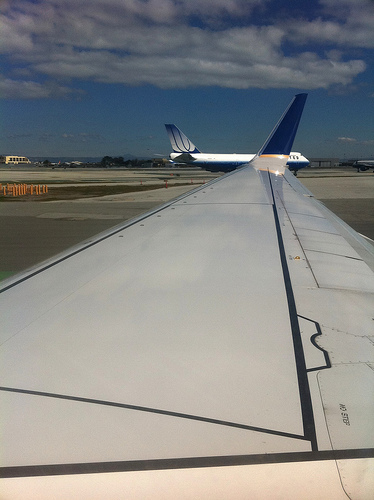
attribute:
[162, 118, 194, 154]
tail — blue, white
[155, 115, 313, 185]
plane — white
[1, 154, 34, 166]
bus — light colored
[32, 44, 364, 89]
cloud — fluffy 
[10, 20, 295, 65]
cloud — fluffy 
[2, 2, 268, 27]
cloud — fluffy 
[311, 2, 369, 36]
cloud — fluffy 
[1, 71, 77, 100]
cloud — fluffy 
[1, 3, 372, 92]
sky — Section 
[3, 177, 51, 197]
poles — big, orange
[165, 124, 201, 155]
logo — white